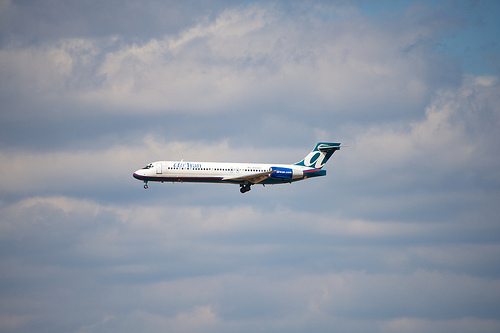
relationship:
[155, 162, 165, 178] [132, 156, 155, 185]
door behind cockpit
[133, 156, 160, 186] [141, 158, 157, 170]
cockpit has windows